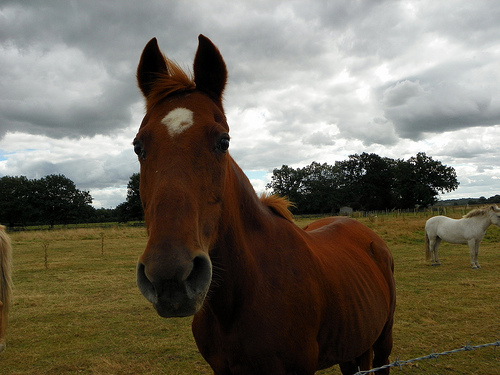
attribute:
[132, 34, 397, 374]
horse — looking, brown, back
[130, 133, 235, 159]
eyes — black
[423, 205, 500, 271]
horse — side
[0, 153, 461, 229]
trees — tall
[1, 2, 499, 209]
sky — cloudy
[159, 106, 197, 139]
spot — white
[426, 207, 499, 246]
coat — white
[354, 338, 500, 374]
fence — wire, gray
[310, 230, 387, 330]
hide — red